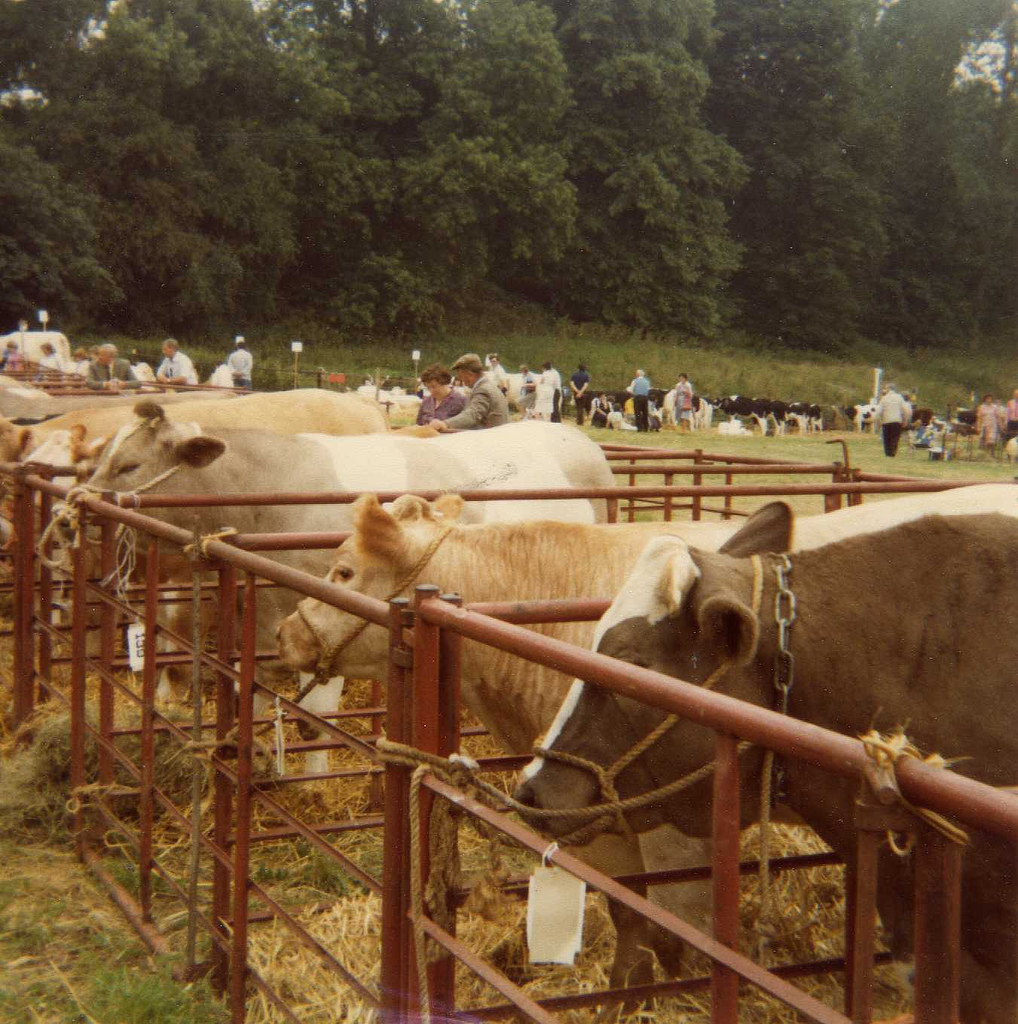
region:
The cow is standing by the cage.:
[490, 537, 1016, 1022]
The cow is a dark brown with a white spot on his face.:
[467, 506, 1010, 1016]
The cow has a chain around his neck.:
[726, 540, 808, 811]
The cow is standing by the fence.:
[269, 492, 1016, 739]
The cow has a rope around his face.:
[253, 499, 469, 688]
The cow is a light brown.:
[252, 483, 1015, 698]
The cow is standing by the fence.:
[58, 397, 632, 604]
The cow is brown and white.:
[64, 406, 658, 595]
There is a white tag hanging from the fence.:
[503, 828, 601, 974]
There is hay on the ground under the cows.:
[18, 646, 809, 1022]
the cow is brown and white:
[522, 513, 1010, 1001]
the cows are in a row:
[0, 378, 1016, 1017]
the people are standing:
[19, 320, 1007, 462]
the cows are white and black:
[595, 388, 827, 435]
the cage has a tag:
[532, 858, 588, 958]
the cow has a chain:
[780, 535, 797, 708]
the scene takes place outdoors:
[0, 0, 1015, 1020]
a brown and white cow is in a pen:
[515, 509, 1010, 1012]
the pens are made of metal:
[12, 439, 1012, 1017]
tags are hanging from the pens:
[121, 609, 593, 972]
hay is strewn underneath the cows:
[0, 589, 906, 1022]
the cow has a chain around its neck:
[524, 502, 827, 846]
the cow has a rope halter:
[266, 490, 555, 731]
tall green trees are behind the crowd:
[10, 6, 1016, 433]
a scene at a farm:
[22, 12, 1010, 996]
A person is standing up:
[874, 385, 904, 459]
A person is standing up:
[975, 394, 1001, 449]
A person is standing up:
[895, 386, 910, 425]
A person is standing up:
[671, 373, 691, 432]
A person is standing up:
[620, 365, 653, 427]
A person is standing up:
[570, 360, 585, 416]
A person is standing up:
[540, 365, 560, 415]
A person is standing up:
[518, 360, 533, 383]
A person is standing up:
[450, 353, 513, 430]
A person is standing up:
[422, 367, 465, 419]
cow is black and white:
[527, 508, 1017, 1019]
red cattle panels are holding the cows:
[3, 365, 1015, 1022]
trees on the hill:
[2, 3, 1012, 368]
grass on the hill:
[64, 318, 1013, 418]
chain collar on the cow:
[759, 532, 801, 827]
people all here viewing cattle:
[15, 329, 1017, 464]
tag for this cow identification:
[521, 838, 596, 977]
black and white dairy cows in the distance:
[576, 375, 831, 440]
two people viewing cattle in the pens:
[400, 353, 504, 430]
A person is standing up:
[628, 366, 651, 434]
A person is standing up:
[675, 378, 699, 423]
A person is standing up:
[864, 376, 904, 437]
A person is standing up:
[575, 366, 601, 418]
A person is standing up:
[543, 362, 570, 411]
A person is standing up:
[522, 359, 552, 408]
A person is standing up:
[458, 356, 497, 417]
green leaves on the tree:
[588, 222, 621, 237]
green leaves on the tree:
[774, 136, 936, 266]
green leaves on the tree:
[848, 246, 888, 311]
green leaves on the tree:
[877, 166, 983, 289]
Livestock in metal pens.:
[25, 368, 1015, 996]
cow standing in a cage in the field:
[522, 494, 1016, 1018]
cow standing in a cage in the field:
[269, 466, 1007, 957]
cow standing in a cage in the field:
[48, 411, 615, 758]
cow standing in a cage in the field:
[20, 383, 387, 644]